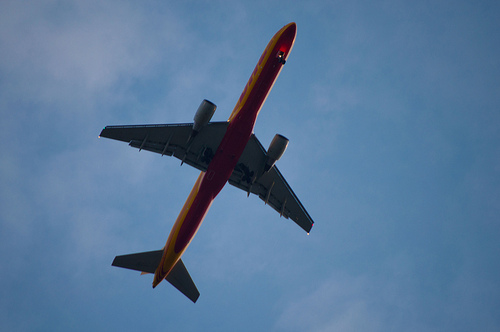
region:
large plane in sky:
[94, 0, 362, 261]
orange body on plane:
[171, 11, 332, 269]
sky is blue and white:
[395, 35, 479, 193]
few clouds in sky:
[14, 34, 198, 135]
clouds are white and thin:
[28, 15, 215, 105]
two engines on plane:
[160, 90, 321, 184]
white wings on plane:
[130, 117, 302, 231]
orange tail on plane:
[68, 200, 203, 321]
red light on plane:
[264, 27, 289, 74]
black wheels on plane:
[274, 50, 294, 69]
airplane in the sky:
[96, 4, 319, 315]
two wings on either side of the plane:
[78, 93, 333, 239]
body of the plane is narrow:
[132, 19, 301, 287]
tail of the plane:
[104, 241, 215, 316]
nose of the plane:
[275, 12, 307, 40]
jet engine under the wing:
[257, 125, 304, 179]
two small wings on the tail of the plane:
[102, 241, 218, 318]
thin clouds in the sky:
[1, 1, 499, 330]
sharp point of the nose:
[289, 16, 300, 26]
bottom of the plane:
[65, 5, 352, 315]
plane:
[95, 3, 327, 295]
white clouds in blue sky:
[372, 59, 427, 93]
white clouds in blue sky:
[368, 176, 403, 207]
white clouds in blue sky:
[250, 283, 294, 311]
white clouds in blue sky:
[397, 82, 434, 127]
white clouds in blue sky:
[100, 25, 145, 63]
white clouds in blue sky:
[51, 36, 88, 63]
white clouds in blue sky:
[41, 146, 93, 181]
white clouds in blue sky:
[71, 191, 101, 218]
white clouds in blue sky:
[47, 218, 79, 263]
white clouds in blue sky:
[342, 13, 397, 68]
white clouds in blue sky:
[322, 125, 364, 176]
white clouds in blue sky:
[291, 266, 356, 326]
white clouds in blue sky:
[381, 185, 455, 245]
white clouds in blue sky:
[71, 38, 138, 76]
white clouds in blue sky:
[28, 111, 85, 179]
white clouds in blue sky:
[71, 183, 142, 237]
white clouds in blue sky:
[20, 215, 78, 280]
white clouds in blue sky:
[362, 168, 440, 228]